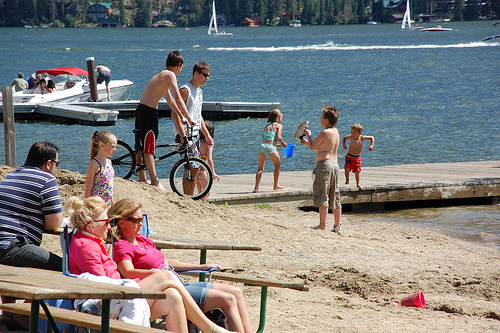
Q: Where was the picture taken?
A: On the beach.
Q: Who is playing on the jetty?
A: A boy and a girl.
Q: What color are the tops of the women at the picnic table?
A: Pink.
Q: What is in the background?
A: 2 sailboats.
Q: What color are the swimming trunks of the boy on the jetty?
A: Red.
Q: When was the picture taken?
A: In Summer.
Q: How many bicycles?
A: 1.